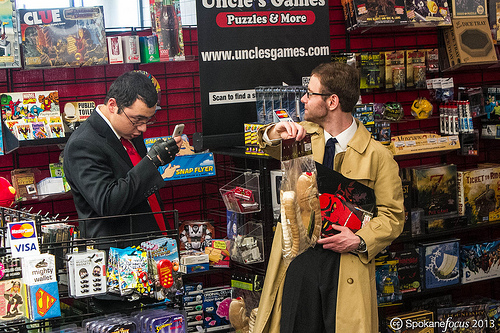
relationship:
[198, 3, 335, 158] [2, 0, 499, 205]
banner on wall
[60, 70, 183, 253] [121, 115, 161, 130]
man wears glasses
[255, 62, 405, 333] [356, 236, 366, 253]
man wears watch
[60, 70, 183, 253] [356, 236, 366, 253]
man wears watch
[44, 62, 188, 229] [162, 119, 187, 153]
man holds cell phone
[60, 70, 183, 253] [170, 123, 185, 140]
man looking at h phone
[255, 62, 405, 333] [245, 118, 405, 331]
man wearing coat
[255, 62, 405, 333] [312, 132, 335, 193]
man wearing tie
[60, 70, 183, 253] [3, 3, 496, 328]
man standing store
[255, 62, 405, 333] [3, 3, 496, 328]
man standing store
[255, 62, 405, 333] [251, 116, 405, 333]
man wearing coat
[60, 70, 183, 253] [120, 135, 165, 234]
man wearing tie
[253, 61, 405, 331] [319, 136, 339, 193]
man wearing tie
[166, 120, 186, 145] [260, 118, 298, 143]
cell phone in hand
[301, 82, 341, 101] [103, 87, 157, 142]
glasses on mans face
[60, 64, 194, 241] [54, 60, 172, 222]
hair on man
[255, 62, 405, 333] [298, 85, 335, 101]
man wearing glasses